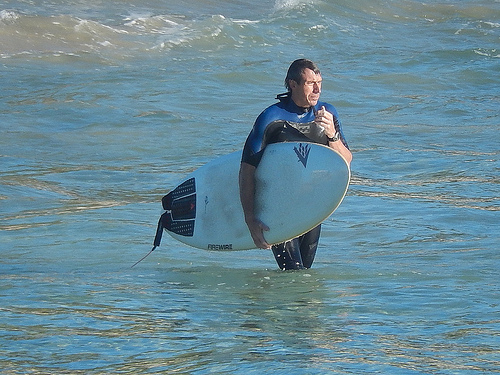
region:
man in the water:
[143, 37, 368, 303]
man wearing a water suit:
[128, 51, 370, 284]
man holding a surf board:
[141, 38, 366, 325]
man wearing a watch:
[121, 43, 397, 299]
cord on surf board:
[120, 248, 170, 265]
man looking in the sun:
[89, 49, 381, 315]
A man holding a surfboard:
[150, 29, 392, 274]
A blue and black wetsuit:
[243, 90, 360, 268]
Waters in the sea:
[370, 216, 467, 335]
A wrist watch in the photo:
[312, 119, 346, 151]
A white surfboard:
[155, 145, 345, 257]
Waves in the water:
[82, 9, 182, 46]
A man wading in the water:
[226, 50, 367, 272]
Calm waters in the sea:
[35, 219, 146, 326]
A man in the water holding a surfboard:
[207, 54, 352, 295]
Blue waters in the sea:
[82, 74, 169, 177]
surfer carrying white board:
[157, 53, 362, 293]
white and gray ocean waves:
[11, 15, 62, 67]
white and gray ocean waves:
[361, 296, 409, 320]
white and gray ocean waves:
[48, 288, 92, 309]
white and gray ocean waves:
[161, 272, 238, 317]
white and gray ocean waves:
[27, 102, 84, 126]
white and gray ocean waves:
[27, 148, 81, 193]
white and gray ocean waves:
[120, 43, 191, 94]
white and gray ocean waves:
[340, 18, 392, 80]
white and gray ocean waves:
[375, 59, 475, 150]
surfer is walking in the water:
[238, 59, 354, 270]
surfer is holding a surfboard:
[238, 59, 351, 268]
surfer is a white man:
[239, 59, 354, 269]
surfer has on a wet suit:
[241, 101, 344, 269]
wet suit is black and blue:
[240, 99, 345, 268]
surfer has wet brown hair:
[283, 59, 320, 88]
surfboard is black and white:
[158, 142, 349, 249]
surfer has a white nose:
[312, 82, 319, 93]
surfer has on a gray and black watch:
[328, 130, 340, 143]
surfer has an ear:
[288, 77, 295, 90]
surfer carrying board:
[179, 57, 357, 287]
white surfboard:
[179, 127, 349, 268]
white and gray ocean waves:
[39, 55, 89, 106]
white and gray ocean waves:
[22, 254, 62, 277]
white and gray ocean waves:
[377, 31, 411, 58]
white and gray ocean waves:
[319, 298, 376, 339]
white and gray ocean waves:
[60, 12, 127, 56]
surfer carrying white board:
[155, 46, 362, 293]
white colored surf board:
[155, 142, 345, 269]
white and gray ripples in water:
[21, 285, 53, 306]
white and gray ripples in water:
[394, 258, 441, 292]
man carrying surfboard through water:
[135, 50, 357, 280]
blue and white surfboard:
[141, 136, 350, 252]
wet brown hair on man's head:
[277, 56, 324, 92]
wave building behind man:
[1, 5, 498, 75]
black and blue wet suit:
[233, 90, 356, 283]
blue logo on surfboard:
[285, 140, 320, 170]